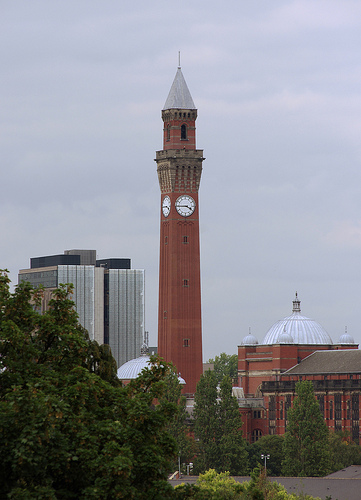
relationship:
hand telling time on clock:
[175, 204, 187, 207] [175, 195, 196, 214]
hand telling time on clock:
[160, 205, 167, 207] [158, 193, 172, 217]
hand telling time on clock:
[185, 206, 194, 211] [175, 195, 196, 214]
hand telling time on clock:
[165, 205, 169, 210] [158, 193, 172, 217]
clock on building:
[175, 194, 194, 215] [153, 51, 206, 392]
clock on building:
[174, 194, 196, 219] [146, 42, 211, 396]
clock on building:
[174, 194, 196, 219] [152, 48, 208, 477]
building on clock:
[155, 42, 214, 400] [174, 194, 196, 217]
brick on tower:
[174, 250, 185, 257] [154, 47, 207, 395]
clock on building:
[174, 194, 196, 219] [152, 51, 205, 396]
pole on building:
[177, 47, 183, 67] [152, 51, 205, 396]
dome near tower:
[116, 339, 187, 386] [151, 47, 219, 390]